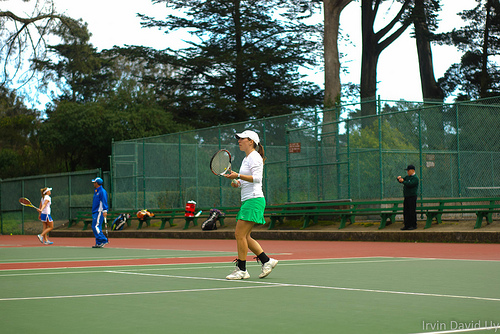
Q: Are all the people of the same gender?
A: No, they are both male and female.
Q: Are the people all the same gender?
A: No, they are both male and female.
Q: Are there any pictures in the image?
A: No, there are no pictures.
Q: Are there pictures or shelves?
A: No, there are no pictures or shelves.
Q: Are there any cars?
A: No, there are no cars.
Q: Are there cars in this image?
A: No, there are no cars.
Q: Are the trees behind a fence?
A: Yes, the trees are behind a fence.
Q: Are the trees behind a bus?
A: No, the trees are behind a fence.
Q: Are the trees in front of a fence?
A: No, the trees are behind a fence.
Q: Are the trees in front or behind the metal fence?
A: The trees are behind the fence.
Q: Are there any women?
A: Yes, there is a woman.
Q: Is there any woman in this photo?
A: Yes, there is a woman.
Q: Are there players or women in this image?
A: Yes, there is a woman.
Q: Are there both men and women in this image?
A: Yes, there are both a woman and a man.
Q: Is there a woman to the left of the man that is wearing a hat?
A: Yes, there is a woman to the left of the man.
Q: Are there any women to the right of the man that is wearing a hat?
A: No, the woman is to the left of the man.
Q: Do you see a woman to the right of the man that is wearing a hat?
A: No, the woman is to the left of the man.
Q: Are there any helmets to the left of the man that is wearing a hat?
A: No, there is a woman to the left of the man.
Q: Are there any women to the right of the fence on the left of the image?
A: Yes, there is a woman to the right of the fence.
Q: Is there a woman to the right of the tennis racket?
A: Yes, there is a woman to the right of the tennis racket.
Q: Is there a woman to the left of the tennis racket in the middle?
A: No, the woman is to the right of the racket.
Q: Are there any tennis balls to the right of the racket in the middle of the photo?
A: No, there is a woman to the right of the racket.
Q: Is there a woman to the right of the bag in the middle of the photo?
A: Yes, there is a woman to the right of the bag.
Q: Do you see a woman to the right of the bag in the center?
A: Yes, there is a woman to the right of the bag.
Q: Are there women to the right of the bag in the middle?
A: Yes, there is a woman to the right of the bag.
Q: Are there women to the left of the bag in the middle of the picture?
A: No, the woman is to the right of the bag.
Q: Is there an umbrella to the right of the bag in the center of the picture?
A: No, there is a woman to the right of the bag.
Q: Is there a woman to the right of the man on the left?
A: Yes, there is a woman to the right of the man.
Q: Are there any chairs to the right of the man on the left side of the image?
A: No, there is a woman to the right of the man.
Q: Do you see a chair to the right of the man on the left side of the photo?
A: No, there is a woman to the right of the man.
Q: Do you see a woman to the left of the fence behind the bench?
A: Yes, there is a woman to the left of the fence.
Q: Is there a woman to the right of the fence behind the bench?
A: No, the woman is to the left of the fence.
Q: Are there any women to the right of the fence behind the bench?
A: No, the woman is to the left of the fence.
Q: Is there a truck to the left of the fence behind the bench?
A: No, there is a woman to the left of the fence.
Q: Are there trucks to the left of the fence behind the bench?
A: No, there is a woman to the left of the fence.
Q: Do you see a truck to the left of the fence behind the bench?
A: No, there is a woman to the left of the fence.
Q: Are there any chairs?
A: No, there are no chairs.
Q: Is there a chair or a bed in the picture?
A: No, there are no chairs or beds.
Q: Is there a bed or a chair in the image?
A: No, there are no chairs or beds.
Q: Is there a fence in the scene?
A: Yes, there is a fence.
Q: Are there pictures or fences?
A: Yes, there is a fence.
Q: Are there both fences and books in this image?
A: No, there is a fence but no books.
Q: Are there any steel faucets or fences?
A: Yes, there is a steel fence.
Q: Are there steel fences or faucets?
A: Yes, there is a steel fence.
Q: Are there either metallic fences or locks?
A: Yes, there is a metal fence.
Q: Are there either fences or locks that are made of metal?
A: Yes, the fence is made of metal.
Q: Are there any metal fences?
A: Yes, there is a metal fence.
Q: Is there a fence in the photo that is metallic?
A: Yes, there is a fence that is metallic.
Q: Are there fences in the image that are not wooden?
A: Yes, there is a metallic fence.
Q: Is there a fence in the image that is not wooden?
A: Yes, there is a metallic fence.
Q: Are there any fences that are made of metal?
A: Yes, there is a fence that is made of metal.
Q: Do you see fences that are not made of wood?
A: Yes, there is a fence that is made of metal.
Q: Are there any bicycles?
A: No, there are no bicycles.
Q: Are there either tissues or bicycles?
A: No, there are no bicycles or tissues.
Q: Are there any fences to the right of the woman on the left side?
A: Yes, there is a fence to the right of the woman.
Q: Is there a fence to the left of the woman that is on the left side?
A: No, the fence is to the right of the woman.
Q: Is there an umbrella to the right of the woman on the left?
A: No, there is a fence to the right of the woman.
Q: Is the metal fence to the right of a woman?
A: Yes, the fence is to the right of a woman.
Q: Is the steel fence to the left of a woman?
A: No, the fence is to the right of a woman.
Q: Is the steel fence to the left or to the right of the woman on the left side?
A: The fence is to the right of the woman.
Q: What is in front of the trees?
A: The fence is in front of the trees.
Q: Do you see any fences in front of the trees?
A: Yes, there is a fence in front of the trees.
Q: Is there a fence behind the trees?
A: No, the fence is in front of the trees.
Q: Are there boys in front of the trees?
A: No, there is a fence in front of the trees.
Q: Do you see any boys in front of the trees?
A: No, there is a fence in front of the trees.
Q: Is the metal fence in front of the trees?
A: Yes, the fence is in front of the trees.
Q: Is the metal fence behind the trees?
A: No, the fence is in front of the trees.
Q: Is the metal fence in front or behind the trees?
A: The fence is in front of the trees.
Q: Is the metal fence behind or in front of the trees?
A: The fence is in front of the trees.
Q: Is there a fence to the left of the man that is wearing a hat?
A: Yes, there is a fence to the left of the man.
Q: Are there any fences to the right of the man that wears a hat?
A: No, the fence is to the left of the man.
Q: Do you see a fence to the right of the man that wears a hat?
A: No, the fence is to the left of the man.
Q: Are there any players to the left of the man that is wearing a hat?
A: No, there is a fence to the left of the man.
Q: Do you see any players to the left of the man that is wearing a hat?
A: No, there is a fence to the left of the man.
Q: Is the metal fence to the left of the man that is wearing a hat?
A: Yes, the fence is to the left of the man.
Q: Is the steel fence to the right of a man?
A: No, the fence is to the left of a man.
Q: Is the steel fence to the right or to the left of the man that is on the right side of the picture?
A: The fence is to the left of the man.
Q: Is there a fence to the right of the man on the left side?
A: Yes, there is a fence to the right of the man.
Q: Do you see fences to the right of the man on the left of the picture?
A: Yes, there is a fence to the right of the man.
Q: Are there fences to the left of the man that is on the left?
A: No, the fence is to the right of the man.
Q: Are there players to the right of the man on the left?
A: No, there is a fence to the right of the man.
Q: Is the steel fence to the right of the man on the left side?
A: Yes, the fence is to the right of the man.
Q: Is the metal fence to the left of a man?
A: No, the fence is to the right of a man.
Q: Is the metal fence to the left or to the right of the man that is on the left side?
A: The fence is to the right of the man.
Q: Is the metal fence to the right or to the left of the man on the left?
A: The fence is to the right of the man.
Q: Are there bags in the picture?
A: Yes, there is a bag.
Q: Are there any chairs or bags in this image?
A: Yes, there is a bag.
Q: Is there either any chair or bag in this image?
A: Yes, there is a bag.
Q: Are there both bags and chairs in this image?
A: No, there is a bag but no chairs.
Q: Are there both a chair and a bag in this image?
A: No, there is a bag but no chairs.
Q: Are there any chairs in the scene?
A: No, there are no chairs.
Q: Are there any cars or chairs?
A: No, there are no chairs or cars.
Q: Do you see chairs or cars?
A: No, there are no chairs or cars.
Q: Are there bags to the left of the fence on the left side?
A: No, the bag is to the right of the fence.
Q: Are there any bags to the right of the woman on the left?
A: Yes, there is a bag to the right of the woman.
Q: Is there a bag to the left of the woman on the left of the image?
A: No, the bag is to the right of the woman.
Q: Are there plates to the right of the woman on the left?
A: No, there is a bag to the right of the woman.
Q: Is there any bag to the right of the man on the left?
A: Yes, there is a bag to the right of the man.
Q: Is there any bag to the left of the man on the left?
A: No, the bag is to the right of the man.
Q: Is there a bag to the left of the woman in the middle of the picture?
A: Yes, there is a bag to the left of the woman.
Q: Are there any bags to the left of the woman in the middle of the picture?
A: Yes, there is a bag to the left of the woman.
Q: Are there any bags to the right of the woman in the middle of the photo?
A: No, the bag is to the left of the woman.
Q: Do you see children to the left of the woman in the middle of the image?
A: No, there is a bag to the left of the woman.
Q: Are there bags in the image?
A: Yes, there is a bag.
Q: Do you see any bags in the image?
A: Yes, there is a bag.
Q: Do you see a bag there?
A: Yes, there is a bag.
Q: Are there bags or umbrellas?
A: Yes, there is a bag.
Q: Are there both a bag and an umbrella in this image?
A: No, there is a bag but no umbrellas.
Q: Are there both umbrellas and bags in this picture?
A: No, there is a bag but no umbrellas.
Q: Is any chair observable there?
A: No, there are no chairs.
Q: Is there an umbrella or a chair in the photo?
A: No, there are no chairs or umbrellas.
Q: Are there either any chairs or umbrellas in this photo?
A: No, there are no chairs or umbrellas.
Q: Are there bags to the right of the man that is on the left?
A: Yes, there is a bag to the right of the man.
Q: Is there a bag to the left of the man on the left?
A: No, the bag is to the right of the man.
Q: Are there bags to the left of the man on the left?
A: No, the bag is to the right of the man.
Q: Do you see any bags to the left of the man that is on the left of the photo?
A: No, the bag is to the right of the man.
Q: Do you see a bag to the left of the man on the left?
A: No, the bag is to the right of the man.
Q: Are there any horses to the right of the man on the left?
A: No, there is a bag to the right of the man.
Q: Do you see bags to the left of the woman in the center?
A: Yes, there is a bag to the left of the woman.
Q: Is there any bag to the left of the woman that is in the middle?
A: Yes, there is a bag to the left of the woman.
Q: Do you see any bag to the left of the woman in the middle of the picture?
A: Yes, there is a bag to the left of the woman.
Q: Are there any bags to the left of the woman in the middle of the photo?
A: Yes, there is a bag to the left of the woman.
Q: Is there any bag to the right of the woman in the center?
A: No, the bag is to the left of the woman.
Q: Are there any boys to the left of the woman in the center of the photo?
A: No, there is a bag to the left of the woman.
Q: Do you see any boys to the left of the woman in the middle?
A: No, there is a bag to the left of the woman.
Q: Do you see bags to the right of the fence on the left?
A: Yes, there is a bag to the right of the fence.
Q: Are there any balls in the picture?
A: No, there are no balls.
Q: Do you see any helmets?
A: No, there are no helmets.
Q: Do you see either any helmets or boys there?
A: No, there are no helmets or boys.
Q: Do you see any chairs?
A: No, there are no chairs.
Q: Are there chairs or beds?
A: No, there are no chairs or beds.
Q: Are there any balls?
A: No, there are no balls.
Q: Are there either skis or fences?
A: Yes, there is a fence.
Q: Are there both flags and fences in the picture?
A: No, there is a fence but no flags.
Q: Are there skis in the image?
A: No, there are no skis.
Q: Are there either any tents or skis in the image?
A: No, there are no skis or tents.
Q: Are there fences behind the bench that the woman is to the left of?
A: Yes, there is a fence behind the bench.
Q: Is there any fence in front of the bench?
A: No, the fence is behind the bench.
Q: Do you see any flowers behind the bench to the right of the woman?
A: No, there is a fence behind the bench.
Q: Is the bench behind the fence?
A: No, the fence is behind the bench.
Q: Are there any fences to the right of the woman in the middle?
A: Yes, there is a fence to the right of the woman.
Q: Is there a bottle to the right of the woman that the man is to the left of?
A: No, there is a fence to the right of the woman.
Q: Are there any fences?
A: Yes, there is a fence.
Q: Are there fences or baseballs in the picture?
A: Yes, there is a fence.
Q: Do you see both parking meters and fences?
A: No, there is a fence but no parking meters.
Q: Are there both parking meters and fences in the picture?
A: No, there is a fence but no parking meters.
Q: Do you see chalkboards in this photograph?
A: No, there are no chalkboards.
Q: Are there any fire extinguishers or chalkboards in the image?
A: No, there are no chalkboards or fire extinguishers.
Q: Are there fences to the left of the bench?
A: Yes, there is a fence to the left of the bench.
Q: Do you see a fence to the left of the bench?
A: Yes, there is a fence to the left of the bench.